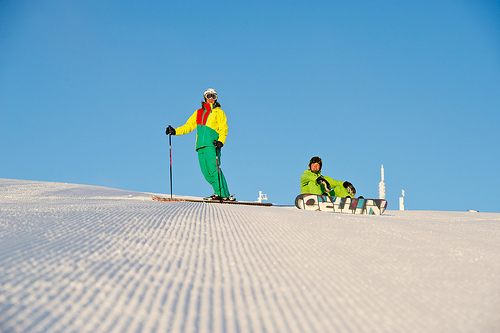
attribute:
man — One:
[301, 159, 356, 207]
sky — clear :
[24, 6, 484, 88]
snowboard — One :
[295, 184, 390, 211]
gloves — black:
[157, 114, 231, 151]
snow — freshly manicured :
[5, 206, 341, 331]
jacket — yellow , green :
[175, 99, 227, 146]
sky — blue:
[3, 1, 499, 216]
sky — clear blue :
[86, 26, 470, 154]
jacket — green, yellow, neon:
[286, 166, 371, 204]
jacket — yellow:
[169, 111, 243, 153]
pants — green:
[181, 134, 239, 199]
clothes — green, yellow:
[171, 100, 417, 245]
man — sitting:
[293, 150, 378, 214]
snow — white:
[293, 215, 379, 231]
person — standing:
[182, 70, 228, 109]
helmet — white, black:
[184, 85, 229, 114]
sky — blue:
[30, 32, 119, 124]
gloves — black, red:
[150, 119, 235, 165]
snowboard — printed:
[285, 185, 405, 218]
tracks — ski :
[111, 219, 286, 330]